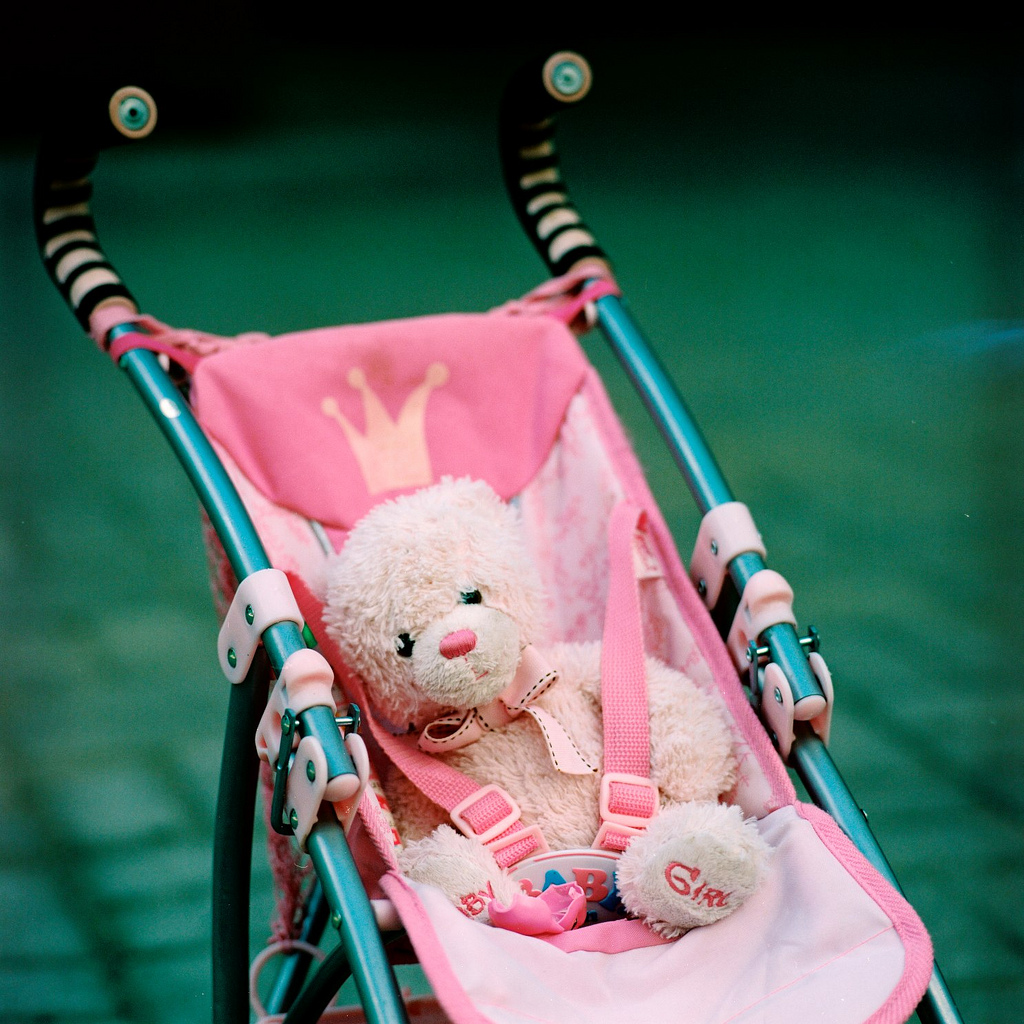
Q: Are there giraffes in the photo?
A: No, there are no giraffes.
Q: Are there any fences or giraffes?
A: No, there are no giraffes or fences.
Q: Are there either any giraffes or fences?
A: No, there are no giraffes or fences.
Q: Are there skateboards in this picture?
A: No, there are no skateboards.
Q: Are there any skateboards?
A: No, there are no skateboards.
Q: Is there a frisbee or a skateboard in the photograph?
A: No, there are no skateboards or frisbees.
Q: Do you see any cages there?
A: No, there are no cages.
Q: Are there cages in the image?
A: No, there are no cages.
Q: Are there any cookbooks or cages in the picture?
A: No, there are no cages or cookbooks.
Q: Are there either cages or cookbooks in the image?
A: No, there are no cages or cookbooks.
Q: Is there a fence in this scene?
A: No, there are no fences.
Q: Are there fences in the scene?
A: No, there are no fences.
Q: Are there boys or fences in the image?
A: No, there are no fences or boys.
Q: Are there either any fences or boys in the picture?
A: No, there are no fences or boys.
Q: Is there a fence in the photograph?
A: No, there are no fences.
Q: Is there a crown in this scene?
A: Yes, there is a crown.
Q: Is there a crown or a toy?
A: Yes, there is a crown.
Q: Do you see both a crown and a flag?
A: No, there is a crown but no flags.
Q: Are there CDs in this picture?
A: No, there are no cds.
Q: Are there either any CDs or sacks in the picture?
A: No, there are no CDs or sacks.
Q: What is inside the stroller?
A: The crown is inside the stroller.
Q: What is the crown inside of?
A: The crown is inside the stroller.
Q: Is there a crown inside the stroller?
A: Yes, there is a crown inside the stroller.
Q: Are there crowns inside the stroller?
A: Yes, there is a crown inside the stroller.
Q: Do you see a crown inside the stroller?
A: Yes, there is a crown inside the stroller.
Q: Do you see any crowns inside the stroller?
A: Yes, there is a crown inside the stroller.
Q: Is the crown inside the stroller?
A: Yes, the crown is inside the stroller.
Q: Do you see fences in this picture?
A: No, there are no fences.